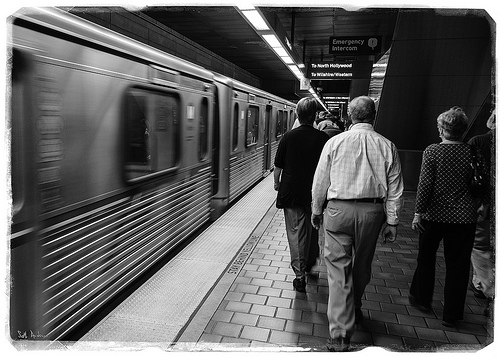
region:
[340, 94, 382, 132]
head of a person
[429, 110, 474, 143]
head of a person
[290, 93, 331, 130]
head of a person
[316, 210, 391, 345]
leg of a person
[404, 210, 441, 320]
leg of a person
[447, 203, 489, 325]
leg of a person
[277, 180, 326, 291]
leg of a person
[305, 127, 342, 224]
arm of a person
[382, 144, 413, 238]
arm of a person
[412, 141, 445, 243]
arm of a person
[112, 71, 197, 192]
window on side of train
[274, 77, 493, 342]
people walking on train station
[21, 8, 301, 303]
train stopped at train station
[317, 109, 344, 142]
person walking alongside train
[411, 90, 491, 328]
person walking alongside train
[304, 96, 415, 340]
person walking alongside train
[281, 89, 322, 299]
person walking alongside train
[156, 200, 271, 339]
safety stay behind zone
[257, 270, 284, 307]
tile on station floor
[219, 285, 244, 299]
tile on station floor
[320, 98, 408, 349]
this is a person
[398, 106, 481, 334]
this is a person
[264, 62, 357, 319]
this is a person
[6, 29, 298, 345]
this is a train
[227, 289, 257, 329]
these are blocks on the ground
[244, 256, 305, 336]
these are blocks on the ground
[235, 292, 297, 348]
these are blocks on the ground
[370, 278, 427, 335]
these are blocks on the ground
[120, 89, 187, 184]
this is a window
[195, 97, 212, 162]
this is a window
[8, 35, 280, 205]
train on the track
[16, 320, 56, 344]
artist credit for image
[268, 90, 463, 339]
people on the track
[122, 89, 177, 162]
window on the train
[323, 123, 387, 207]
shirt on the man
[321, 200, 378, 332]
pants on the man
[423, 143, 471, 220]
blouse on the woman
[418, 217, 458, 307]
pants on the woman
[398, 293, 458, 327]
shoes on the woman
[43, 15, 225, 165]
Train parked in the railway station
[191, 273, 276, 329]
Platform of the railway station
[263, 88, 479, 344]
Peoples walking in the platform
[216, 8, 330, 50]
Roof of the railway station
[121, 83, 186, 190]
Window of the train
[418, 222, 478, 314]
A woman wearing black color pant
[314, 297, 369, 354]
Pair of shoes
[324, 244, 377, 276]
Legs of the person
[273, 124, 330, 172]
A person wearing black color round neck t-shirt